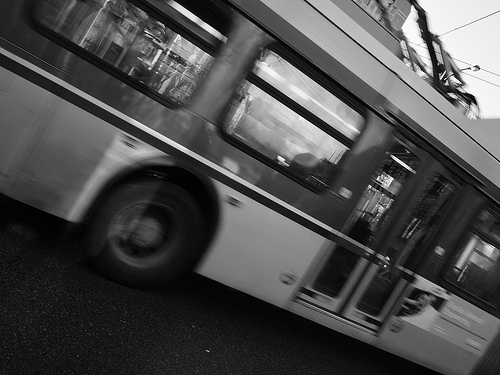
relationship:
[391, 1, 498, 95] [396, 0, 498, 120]
wires in sky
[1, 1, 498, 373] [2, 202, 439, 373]
bus on street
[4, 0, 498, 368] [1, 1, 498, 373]
photo of a bus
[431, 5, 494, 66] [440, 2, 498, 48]
lines in sky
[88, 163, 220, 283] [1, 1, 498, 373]
wheel to bus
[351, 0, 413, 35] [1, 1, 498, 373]
building behind bus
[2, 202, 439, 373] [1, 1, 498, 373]
street under bus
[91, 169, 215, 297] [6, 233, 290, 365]
bus on road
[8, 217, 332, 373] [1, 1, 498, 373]
road with bus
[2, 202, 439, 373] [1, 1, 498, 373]
street with a bus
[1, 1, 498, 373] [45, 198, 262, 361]
bus on road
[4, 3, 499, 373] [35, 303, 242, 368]
passenger bus on street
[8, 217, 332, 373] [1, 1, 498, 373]
road with a bus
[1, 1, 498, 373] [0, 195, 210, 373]
bus on road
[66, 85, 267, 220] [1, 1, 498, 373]
reflection on bus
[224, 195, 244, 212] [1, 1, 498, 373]
light on bus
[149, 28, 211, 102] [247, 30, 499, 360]
window on bus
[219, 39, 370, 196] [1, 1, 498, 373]
window on bus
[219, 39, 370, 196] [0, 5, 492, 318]
window on bus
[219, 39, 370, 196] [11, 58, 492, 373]
window on bus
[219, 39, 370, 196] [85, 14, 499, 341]
window on bus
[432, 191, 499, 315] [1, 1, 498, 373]
window on bus